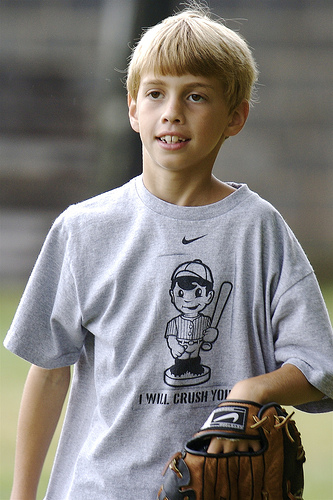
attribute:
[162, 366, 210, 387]
base — under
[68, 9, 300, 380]
young boy — wearing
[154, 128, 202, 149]
mouth — open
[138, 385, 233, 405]
text — black